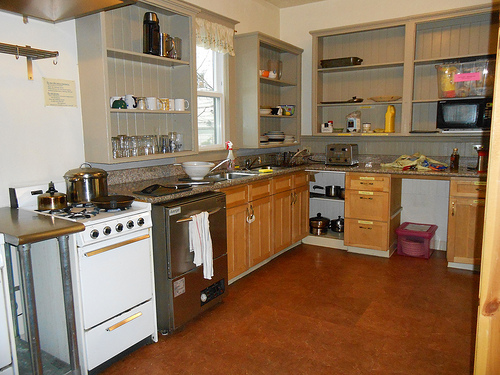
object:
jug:
[384, 103, 394, 132]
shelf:
[316, 99, 403, 105]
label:
[451, 70, 479, 83]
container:
[433, 57, 495, 99]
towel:
[186, 208, 213, 281]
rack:
[174, 206, 226, 224]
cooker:
[63, 162, 112, 206]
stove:
[34, 200, 159, 375]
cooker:
[310, 185, 342, 200]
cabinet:
[452, 207, 483, 256]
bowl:
[179, 162, 217, 183]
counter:
[109, 166, 305, 198]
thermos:
[140, 13, 164, 56]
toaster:
[324, 143, 361, 167]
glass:
[111, 147, 121, 156]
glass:
[122, 145, 130, 154]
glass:
[137, 143, 144, 153]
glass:
[139, 136, 151, 144]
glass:
[145, 140, 155, 154]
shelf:
[110, 109, 191, 115]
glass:
[150, 142, 154, 151]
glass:
[159, 140, 173, 148]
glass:
[172, 140, 179, 147]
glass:
[169, 148, 180, 152]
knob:
[86, 228, 101, 241]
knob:
[115, 222, 125, 231]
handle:
[84, 234, 150, 255]